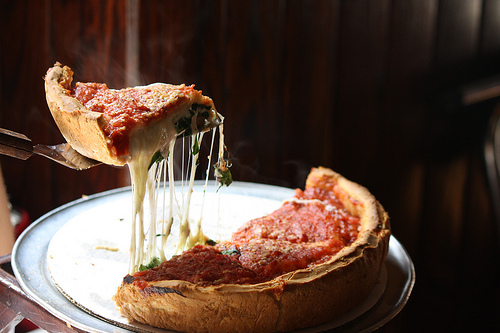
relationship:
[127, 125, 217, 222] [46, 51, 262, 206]
cheese coming off food